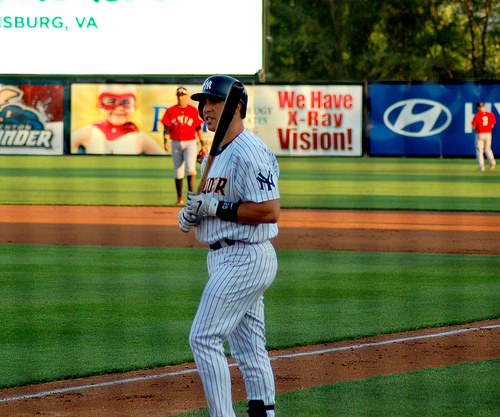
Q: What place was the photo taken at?
A: It was taken at the field.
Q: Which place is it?
A: It is a field.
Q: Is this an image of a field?
A: Yes, it is showing a field.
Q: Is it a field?
A: Yes, it is a field.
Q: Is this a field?
A: Yes, it is a field.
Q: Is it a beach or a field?
A: It is a field.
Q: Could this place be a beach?
A: No, it is a field.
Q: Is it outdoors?
A: Yes, it is outdoors.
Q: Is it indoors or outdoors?
A: It is outdoors.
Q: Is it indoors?
A: No, it is outdoors.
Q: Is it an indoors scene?
A: No, it is outdoors.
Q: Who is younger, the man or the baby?
A: The baby is younger than the man.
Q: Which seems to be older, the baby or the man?
A: The man is older than the baby.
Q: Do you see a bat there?
A: Yes, there is a bat.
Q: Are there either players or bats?
A: Yes, there is a bat.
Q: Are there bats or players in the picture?
A: Yes, there is a bat.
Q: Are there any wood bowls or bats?
A: Yes, there is a wood bat.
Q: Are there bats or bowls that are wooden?
A: Yes, the bat is wooden.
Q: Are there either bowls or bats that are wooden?
A: Yes, the bat is wooden.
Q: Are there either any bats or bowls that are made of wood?
A: Yes, the bat is made of wood.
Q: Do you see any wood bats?
A: Yes, there is a wood bat.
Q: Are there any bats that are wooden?
A: Yes, there is a bat that is wooden.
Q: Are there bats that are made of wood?
A: Yes, there is a bat that is made of wood.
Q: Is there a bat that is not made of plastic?
A: Yes, there is a bat that is made of wood.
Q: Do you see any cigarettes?
A: No, there are no cigarettes.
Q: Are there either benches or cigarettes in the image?
A: No, there are no cigarettes or benches.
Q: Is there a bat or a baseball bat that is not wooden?
A: No, there is a bat but it is wooden.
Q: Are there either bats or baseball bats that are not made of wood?
A: No, there is a bat but it is made of wood.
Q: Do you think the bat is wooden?
A: Yes, the bat is wooden.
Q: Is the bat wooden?
A: Yes, the bat is wooden.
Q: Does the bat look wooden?
A: Yes, the bat is wooden.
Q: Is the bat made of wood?
A: Yes, the bat is made of wood.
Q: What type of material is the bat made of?
A: The bat is made of wood.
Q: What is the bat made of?
A: The bat is made of wood.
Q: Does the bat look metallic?
A: No, the bat is wooden.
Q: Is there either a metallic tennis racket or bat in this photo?
A: No, there is a bat but it is wooden.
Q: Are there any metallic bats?
A: No, there is a bat but it is wooden.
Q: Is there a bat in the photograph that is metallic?
A: No, there is a bat but it is wooden.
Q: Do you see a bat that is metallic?
A: No, there is a bat but it is wooden.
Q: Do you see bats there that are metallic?
A: No, there is a bat but it is wooden.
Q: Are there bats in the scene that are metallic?
A: No, there is a bat but it is wooden.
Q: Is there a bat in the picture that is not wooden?
A: No, there is a bat but it is wooden.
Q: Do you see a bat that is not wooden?
A: No, there is a bat but it is wooden.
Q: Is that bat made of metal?
A: No, the bat is made of wood.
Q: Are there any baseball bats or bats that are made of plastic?
A: No, there is a bat but it is made of wood.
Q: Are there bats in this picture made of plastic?
A: No, there is a bat but it is made of wood.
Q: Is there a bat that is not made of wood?
A: No, there is a bat but it is made of wood.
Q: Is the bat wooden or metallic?
A: The bat is wooden.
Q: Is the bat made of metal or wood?
A: The bat is made of wood.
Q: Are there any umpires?
A: No, there are no umpires.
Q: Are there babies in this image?
A: Yes, there is a baby.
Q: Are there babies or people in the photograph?
A: Yes, there is a baby.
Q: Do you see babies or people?
A: Yes, there is a baby.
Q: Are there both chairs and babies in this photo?
A: No, there is a baby but no chairs.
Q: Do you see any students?
A: No, there are no students.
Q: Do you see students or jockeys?
A: No, there are no students or jockeys.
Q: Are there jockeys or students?
A: No, there are no students or jockeys.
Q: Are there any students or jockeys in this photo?
A: No, there are no students or jockeys.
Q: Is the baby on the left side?
A: Yes, the baby is on the left of the image.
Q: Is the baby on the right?
A: No, the baby is on the left of the image.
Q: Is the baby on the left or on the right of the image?
A: The baby is on the left of the image.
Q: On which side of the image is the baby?
A: The baby is on the left of the image.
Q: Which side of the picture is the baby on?
A: The baby is on the left of the image.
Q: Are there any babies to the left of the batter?
A: Yes, there is a baby to the left of the batter.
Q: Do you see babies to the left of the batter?
A: Yes, there is a baby to the left of the batter.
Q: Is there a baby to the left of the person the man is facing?
A: Yes, there is a baby to the left of the batter.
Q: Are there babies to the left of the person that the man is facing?
A: Yes, there is a baby to the left of the batter.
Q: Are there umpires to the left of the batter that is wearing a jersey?
A: No, there is a baby to the left of the batter.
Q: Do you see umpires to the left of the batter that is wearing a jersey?
A: No, there is a baby to the left of the batter.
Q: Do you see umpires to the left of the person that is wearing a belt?
A: No, there is a baby to the left of the batter.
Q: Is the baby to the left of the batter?
A: Yes, the baby is to the left of the batter.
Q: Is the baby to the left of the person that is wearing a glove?
A: Yes, the baby is to the left of the batter.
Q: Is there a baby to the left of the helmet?
A: Yes, there is a baby to the left of the helmet.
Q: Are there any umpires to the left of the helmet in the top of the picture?
A: No, there is a baby to the left of the helmet.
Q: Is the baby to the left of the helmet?
A: Yes, the baby is to the left of the helmet.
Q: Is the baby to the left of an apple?
A: No, the baby is to the left of the helmet.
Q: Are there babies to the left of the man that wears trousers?
A: Yes, there is a baby to the left of the man.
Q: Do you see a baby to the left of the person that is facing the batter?
A: Yes, there is a baby to the left of the man.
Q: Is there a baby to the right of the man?
A: No, the baby is to the left of the man.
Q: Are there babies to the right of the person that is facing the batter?
A: No, the baby is to the left of the man.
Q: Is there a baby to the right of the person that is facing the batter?
A: No, the baby is to the left of the man.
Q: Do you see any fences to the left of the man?
A: No, there is a baby to the left of the man.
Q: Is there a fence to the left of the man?
A: No, there is a baby to the left of the man.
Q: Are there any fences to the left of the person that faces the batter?
A: No, there is a baby to the left of the man.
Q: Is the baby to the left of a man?
A: Yes, the baby is to the left of a man.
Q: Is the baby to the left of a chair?
A: No, the baby is to the left of a man.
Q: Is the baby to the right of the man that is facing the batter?
A: No, the baby is to the left of the man.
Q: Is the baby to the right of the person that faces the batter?
A: No, the baby is to the left of the man.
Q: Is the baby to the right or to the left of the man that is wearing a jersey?
A: The baby is to the left of the man.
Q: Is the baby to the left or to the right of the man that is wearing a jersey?
A: The baby is to the left of the man.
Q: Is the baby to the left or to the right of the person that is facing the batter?
A: The baby is to the left of the man.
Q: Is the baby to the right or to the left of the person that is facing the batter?
A: The baby is to the left of the man.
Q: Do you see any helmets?
A: Yes, there is a helmet.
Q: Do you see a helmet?
A: Yes, there is a helmet.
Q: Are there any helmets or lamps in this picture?
A: Yes, there is a helmet.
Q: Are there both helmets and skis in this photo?
A: No, there is a helmet but no skis.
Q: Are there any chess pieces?
A: No, there are no chess pieces.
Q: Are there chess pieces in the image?
A: No, there are no chess pieces.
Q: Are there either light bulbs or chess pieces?
A: No, there are no chess pieces or light bulbs.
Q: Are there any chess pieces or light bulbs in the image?
A: No, there are no chess pieces or light bulbs.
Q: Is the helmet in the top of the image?
A: Yes, the helmet is in the top of the image.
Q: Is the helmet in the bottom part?
A: No, the helmet is in the top of the image.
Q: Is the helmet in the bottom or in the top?
A: The helmet is in the top of the image.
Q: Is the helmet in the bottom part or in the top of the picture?
A: The helmet is in the top of the image.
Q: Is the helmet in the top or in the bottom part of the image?
A: The helmet is in the top of the image.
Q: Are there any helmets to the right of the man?
A: Yes, there is a helmet to the right of the man.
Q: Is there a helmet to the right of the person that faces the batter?
A: Yes, there is a helmet to the right of the man.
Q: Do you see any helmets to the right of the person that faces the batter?
A: Yes, there is a helmet to the right of the man.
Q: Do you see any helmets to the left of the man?
A: No, the helmet is to the right of the man.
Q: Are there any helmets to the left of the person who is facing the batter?
A: No, the helmet is to the right of the man.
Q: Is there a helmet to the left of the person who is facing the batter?
A: No, the helmet is to the right of the man.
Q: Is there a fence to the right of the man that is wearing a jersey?
A: No, there is a helmet to the right of the man.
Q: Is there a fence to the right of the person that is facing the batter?
A: No, there is a helmet to the right of the man.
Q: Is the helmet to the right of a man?
A: Yes, the helmet is to the right of a man.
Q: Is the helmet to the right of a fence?
A: No, the helmet is to the right of a man.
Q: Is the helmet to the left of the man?
A: No, the helmet is to the right of the man.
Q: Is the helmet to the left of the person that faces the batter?
A: No, the helmet is to the right of the man.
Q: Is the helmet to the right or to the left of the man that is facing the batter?
A: The helmet is to the right of the man.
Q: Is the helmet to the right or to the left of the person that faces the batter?
A: The helmet is to the right of the man.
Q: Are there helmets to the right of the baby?
A: Yes, there is a helmet to the right of the baby.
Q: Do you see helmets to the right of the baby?
A: Yes, there is a helmet to the right of the baby.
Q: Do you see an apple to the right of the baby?
A: No, there is a helmet to the right of the baby.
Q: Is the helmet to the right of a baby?
A: Yes, the helmet is to the right of a baby.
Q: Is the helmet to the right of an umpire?
A: No, the helmet is to the right of a baby.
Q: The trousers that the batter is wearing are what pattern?
A: The trousers are striped.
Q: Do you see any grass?
A: Yes, there is grass.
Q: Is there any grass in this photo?
A: Yes, there is grass.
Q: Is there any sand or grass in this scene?
A: Yes, there is grass.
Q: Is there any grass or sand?
A: Yes, there is grass.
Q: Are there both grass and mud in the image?
A: No, there is grass but no mud.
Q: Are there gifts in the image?
A: No, there are no gifts.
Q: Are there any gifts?
A: No, there are no gifts.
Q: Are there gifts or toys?
A: No, there are no gifts or toys.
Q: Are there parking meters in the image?
A: No, there are no parking meters.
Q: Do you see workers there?
A: No, there are no workers.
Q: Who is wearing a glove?
A: The batter is wearing a glove.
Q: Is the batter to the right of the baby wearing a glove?
A: Yes, the batter is wearing a glove.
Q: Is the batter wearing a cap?
A: No, the batter is wearing a glove.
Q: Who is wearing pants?
A: The batter is wearing pants.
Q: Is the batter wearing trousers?
A: Yes, the batter is wearing trousers.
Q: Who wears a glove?
A: The batter wears a glove.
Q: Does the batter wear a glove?
A: Yes, the batter wears a glove.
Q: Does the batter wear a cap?
A: No, the batter wears a glove.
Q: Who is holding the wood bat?
A: The batter is holding the bat.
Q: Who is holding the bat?
A: The batter is holding the bat.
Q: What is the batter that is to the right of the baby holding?
A: The batter is holding the bat.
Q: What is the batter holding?
A: The batter is holding the bat.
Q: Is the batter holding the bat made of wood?
A: Yes, the batter is holding the bat.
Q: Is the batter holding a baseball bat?
A: No, the batter is holding the bat.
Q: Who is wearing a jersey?
A: The batter is wearing a jersey.